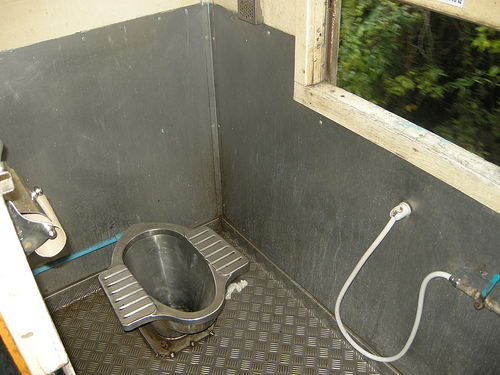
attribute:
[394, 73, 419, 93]
leaves — green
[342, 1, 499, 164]
leaves — green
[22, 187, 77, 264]
pipe — white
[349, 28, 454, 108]
leaves — green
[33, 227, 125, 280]
pipe — attached, blue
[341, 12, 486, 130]
trees — green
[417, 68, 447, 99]
leaves — green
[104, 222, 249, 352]
toilet — silver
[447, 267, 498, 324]
pipe — gray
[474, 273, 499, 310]
pipe — blue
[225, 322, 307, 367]
stainless — steel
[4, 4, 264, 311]
wall — stainless steel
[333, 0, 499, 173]
leaves — green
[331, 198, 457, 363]
cord — plugged in, white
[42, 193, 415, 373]
floor — metal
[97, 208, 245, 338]
toilet — stainless steel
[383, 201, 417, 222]
nozzle — white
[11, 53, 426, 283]
wall — metallic, gray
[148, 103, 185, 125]
floor — tiled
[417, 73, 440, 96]
leaves — green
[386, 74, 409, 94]
leaves — green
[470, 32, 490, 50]
leaves — green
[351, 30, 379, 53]
leaves — green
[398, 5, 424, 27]
leaves — green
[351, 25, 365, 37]
leaf — green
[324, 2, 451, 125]
window — open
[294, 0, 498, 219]
window frame — white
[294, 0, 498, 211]
window — painted, white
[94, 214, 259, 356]
toilet — waterless, riveted, metal, gray